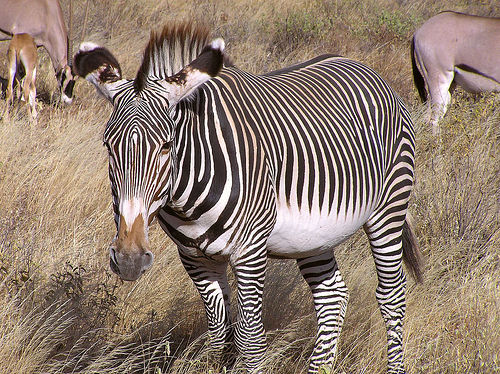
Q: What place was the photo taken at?
A: It was taken at the forest.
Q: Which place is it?
A: It is a forest.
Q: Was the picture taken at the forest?
A: Yes, it was taken in the forest.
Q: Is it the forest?
A: Yes, it is the forest.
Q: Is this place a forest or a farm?
A: It is a forest.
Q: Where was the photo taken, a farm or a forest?
A: It was taken at a forest.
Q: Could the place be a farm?
A: No, it is a forest.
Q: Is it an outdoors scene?
A: Yes, it is outdoors.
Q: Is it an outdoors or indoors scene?
A: It is outdoors.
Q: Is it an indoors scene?
A: No, it is outdoors.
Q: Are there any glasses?
A: No, there are no glasses.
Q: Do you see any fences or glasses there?
A: No, there are no glasses or fences.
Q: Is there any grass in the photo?
A: Yes, there is grass.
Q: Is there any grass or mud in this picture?
A: Yes, there is grass.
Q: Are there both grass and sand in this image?
A: No, there is grass but no sand.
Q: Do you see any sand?
A: No, there is no sand.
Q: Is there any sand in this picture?
A: No, there is no sand.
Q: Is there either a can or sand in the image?
A: No, there are no sand or cans.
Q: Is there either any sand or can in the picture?
A: No, there are no sand or cans.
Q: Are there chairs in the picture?
A: No, there are no chairs.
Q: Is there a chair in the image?
A: No, there are no chairs.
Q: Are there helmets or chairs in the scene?
A: No, there are no chairs or helmets.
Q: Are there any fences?
A: No, there are no fences.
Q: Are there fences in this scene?
A: No, there are no fences.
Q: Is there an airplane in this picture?
A: No, there are no airplanes.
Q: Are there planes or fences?
A: No, there are no planes or fences.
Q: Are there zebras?
A: Yes, there is a zebra.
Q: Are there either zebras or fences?
A: Yes, there is a zebra.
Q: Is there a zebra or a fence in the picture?
A: Yes, there is a zebra.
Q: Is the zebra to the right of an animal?
A: Yes, the zebra is to the right of an animal.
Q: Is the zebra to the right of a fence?
A: No, the zebra is to the right of an animal.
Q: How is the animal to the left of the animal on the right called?
A: The animal is a zebra.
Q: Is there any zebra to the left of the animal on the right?
A: Yes, there is a zebra to the left of the animal.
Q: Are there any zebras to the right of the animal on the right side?
A: No, the zebra is to the left of the animal.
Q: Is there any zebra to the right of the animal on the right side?
A: No, the zebra is to the left of the animal.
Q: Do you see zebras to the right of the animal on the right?
A: No, the zebra is to the left of the animal.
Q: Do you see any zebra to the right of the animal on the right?
A: No, the zebra is to the left of the animal.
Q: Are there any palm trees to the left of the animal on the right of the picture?
A: No, there is a zebra to the left of the animal.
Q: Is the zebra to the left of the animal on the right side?
A: Yes, the zebra is to the left of the animal.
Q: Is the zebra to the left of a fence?
A: No, the zebra is to the left of the animal.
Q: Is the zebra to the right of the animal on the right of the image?
A: No, the zebra is to the left of the animal.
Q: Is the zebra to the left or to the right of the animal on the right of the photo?
A: The zebra is to the left of the animal.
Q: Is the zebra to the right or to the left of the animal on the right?
A: The zebra is to the left of the animal.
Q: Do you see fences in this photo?
A: No, there are no fences.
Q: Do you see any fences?
A: No, there are no fences.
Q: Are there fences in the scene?
A: No, there are no fences.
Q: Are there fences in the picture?
A: No, there are no fences.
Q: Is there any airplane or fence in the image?
A: No, there are no fences or airplanes.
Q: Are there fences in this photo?
A: No, there are no fences.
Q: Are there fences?
A: No, there are no fences.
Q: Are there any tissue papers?
A: No, there are no tissue papers.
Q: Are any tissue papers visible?
A: No, there are no tissue papers.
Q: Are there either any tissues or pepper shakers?
A: No, there are no tissues or pepper shakers.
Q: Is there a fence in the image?
A: No, there are no fences.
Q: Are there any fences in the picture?
A: No, there are no fences.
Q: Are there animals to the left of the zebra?
A: Yes, there is an animal to the left of the zebra.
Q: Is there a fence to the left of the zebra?
A: No, there is an animal to the left of the zebra.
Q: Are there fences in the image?
A: No, there are no fences.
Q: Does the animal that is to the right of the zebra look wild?
A: Yes, the animal is wild.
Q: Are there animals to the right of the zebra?
A: Yes, there is an animal to the right of the zebra.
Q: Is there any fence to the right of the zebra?
A: No, there is an animal to the right of the zebra.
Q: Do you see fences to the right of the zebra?
A: No, there is an animal to the right of the zebra.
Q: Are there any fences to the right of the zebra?
A: No, there is an animal to the right of the zebra.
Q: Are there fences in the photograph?
A: No, there are no fences.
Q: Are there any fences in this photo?
A: No, there are no fences.